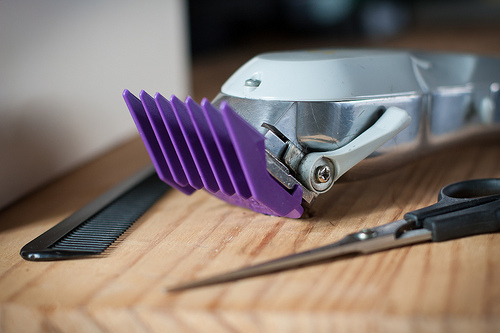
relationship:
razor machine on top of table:
[122, 42, 500, 221] [2, 24, 499, 332]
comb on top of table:
[19, 156, 171, 261] [2, 24, 499, 332]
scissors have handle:
[175, 175, 499, 292] [410, 177, 498, 242]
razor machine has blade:
[122, 42, 500, 221] [122, 86, 308, 220]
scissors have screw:
[175, 175, 499, 292] [358, 228, 373, 240]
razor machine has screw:
[122, 42, 500, 221] [314, 166, 332, 181]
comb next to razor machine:
[19, 156, 171, 261] [122, 42, 500, 221]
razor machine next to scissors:
[122, 42, 500, 221] [175, 175, 499, 292]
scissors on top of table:
[175, 175, 499, 292] [2, 24, 499, 332]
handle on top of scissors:
[410, 177, 498, 242] [175, 175, 499, 292]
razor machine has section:
[122, 42, 500, 221] [218, 47, 496, 193]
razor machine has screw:
[122, 42, 500, 221] [358, 228, 373, 240]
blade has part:
[122, 86, 308, 220] [122, 86, 198, 196]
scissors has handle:
[175, 175, 499, 292] [410, 177, 498, 242]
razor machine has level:
[122, 42, 500, 221] [301, 104, 410, 196]